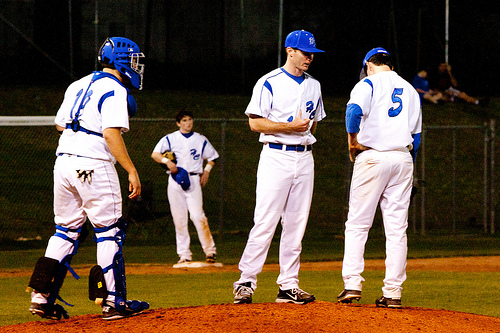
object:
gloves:
[74, 167, 96, 184]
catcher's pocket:
[73, 166, 100, 190]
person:
[151, 112, 220, 259]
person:
[225, 25, 330, 311]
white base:
[138, 215, 275, 277]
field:
[21, 190, 489, 312]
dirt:
[160, 302, 393, 331]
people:
[408, 62, 482, 107]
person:
[338, 37, 431, 309]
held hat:
[169, 164, 191, 192]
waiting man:
[149, 109, 221, 263]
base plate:
[167, 256, 227, 271]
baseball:
[14, 15, 481, 329]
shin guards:
[28, 250, 130, 320]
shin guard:
[88, 252, 129, 306]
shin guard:
[31, 257, 67, 298]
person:
[21, 30, 149, 330]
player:
[335, 45, 422, 309]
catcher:
[24, 26, 154, 316]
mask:
[100, 38, 148, 87]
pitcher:
[242, 16, 341, 318]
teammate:
[334, 43, 433, 300]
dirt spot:
[196, 215, 219, 254]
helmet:
[99, 37, 150, 89]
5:
[387, 83, 404, 120]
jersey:
[339, 69, 426, 150]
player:
[149, 105, 229, 271]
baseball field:
[2, 61, 497, 329]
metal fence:
[419, 117, 497, 239]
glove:
[148, 174, 197, 193]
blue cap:
[169, 167, 192, 191]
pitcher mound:
[0, 304, 497, 331]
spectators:
[404, 61, 493, 112]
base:
[171, 260, 224, 270]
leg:
[187, 200, 233, 260]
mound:
[197, 305, 343, 329]